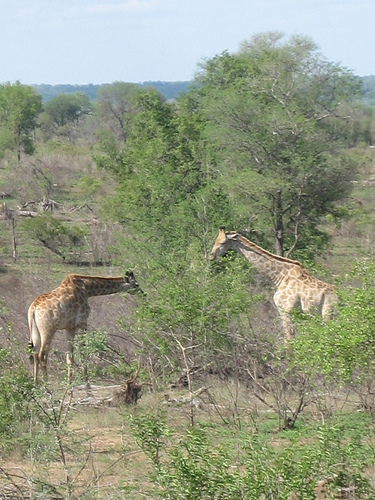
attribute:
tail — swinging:
[30, 298, 38, 363]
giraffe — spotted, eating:
[25, 270, 148, 403]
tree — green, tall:
[78, 32, 371, 369]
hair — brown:
[67, 274, 126, 282]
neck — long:
[74, 273, 125, 298]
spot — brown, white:
[44, 301, 54, 309]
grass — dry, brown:
[1, 377, 374, 500]